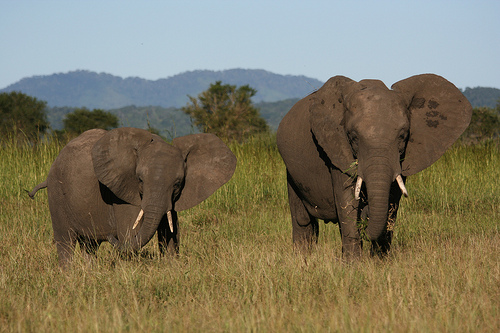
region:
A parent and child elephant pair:
[44, 70, 471, 259]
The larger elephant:
[274, 61, 474, 264]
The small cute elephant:
[23, 124, 240, 257]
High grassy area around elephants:
[0, 146, 499, 328]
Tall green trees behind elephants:
[0, 81, 499, 151]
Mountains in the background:
[1, 65, 499, 120]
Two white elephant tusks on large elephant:
[351, 173, 410, 203]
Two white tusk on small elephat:
[128, 208, 175, 235]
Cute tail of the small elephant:
[25, 178, 47, 203]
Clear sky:
[1, 8, 498, 80]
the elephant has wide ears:
[299, 80, 362, 179]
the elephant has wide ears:
[398, 76, 473, 213]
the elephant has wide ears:
[163, 126, 245, 238]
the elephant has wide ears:
[96, 128, 173, 223]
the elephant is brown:
[246, 63, 468, 325]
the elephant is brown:
[45, 102, 240, 276]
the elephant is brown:
[239, 86, 486, 300]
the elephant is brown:
[256, 41, 487, 323]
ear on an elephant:
[180, 126, 235, 223]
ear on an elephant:
[90, 121, 137, 206]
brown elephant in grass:
[12, 91, 247, 286]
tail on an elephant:
[11, 165, 46, 205]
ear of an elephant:
[305, 80, 356, 170]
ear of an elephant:
[400, 75, 475, 170]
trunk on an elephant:
[361, 127, 383, 257]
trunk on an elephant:
[140, 190, 165, 260]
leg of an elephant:
[285, 180, 320, 265]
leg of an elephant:
[45, 220, 86, 280]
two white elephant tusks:
[127, 207, 175, 235]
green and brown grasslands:
[195, 262, 386, 327]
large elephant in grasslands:
[270, 70, 475, 270]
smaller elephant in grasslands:
[21, 125, 236, 265]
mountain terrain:
[6, 67, 291, 112]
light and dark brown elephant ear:
[402, 71, 472, 168]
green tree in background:
[185, 76, 275, 141]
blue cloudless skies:
[225, 5, 477, 60]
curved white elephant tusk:
[350, 175, 365, 201]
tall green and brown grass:
[230, 130, 275, 211]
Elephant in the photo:
[52, 137, 217, 259]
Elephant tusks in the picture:
[131, 199, 176, 233]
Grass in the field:
[182, 255, 322, 325]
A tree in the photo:
[186, 76, 261, 141]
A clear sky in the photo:
[140, 2, 232, 54]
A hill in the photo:
[147, 58, 277, 90]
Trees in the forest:
[114, 100, 196, 127]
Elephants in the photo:
[32, 59, 476, 269]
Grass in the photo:
[234, 127, 278, 223]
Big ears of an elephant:
[410, 84, 465, 176]